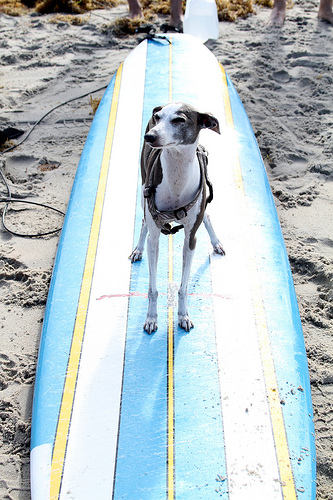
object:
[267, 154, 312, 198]
dips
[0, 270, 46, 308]
dips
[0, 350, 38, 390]
dips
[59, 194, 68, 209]
sand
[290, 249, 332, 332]
dips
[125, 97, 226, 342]
dog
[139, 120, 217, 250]
clothing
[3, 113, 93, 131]
tire tracks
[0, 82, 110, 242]
cord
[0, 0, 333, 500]
beach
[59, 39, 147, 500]
stripes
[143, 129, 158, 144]
nose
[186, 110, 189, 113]
spot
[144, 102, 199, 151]
face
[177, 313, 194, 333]
paws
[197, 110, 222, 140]
ear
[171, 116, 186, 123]
eye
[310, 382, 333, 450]
footprint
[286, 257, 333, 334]
footprint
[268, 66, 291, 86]
footprint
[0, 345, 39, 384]
footprint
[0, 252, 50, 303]
footprint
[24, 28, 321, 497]
board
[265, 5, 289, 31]
foot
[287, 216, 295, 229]
sand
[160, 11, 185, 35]
feet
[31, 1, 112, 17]
seaweed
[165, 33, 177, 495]
stripe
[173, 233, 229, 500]
stripe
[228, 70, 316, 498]
blue stripe